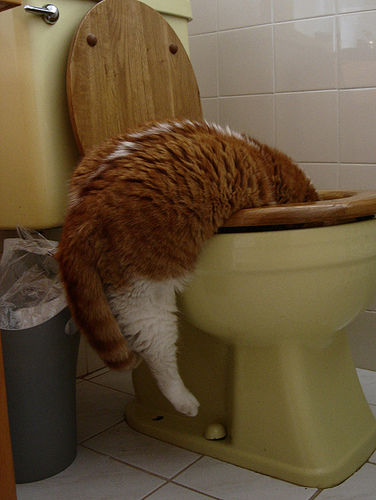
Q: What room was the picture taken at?
A: It was taken at the bathroom.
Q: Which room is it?
A: It is a bathroom.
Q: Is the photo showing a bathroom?
A: Yes, it is showing a bathroom.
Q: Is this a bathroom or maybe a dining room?
A: It is a bathroom.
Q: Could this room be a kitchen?
A: No, it is a bathroom.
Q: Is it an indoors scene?
A: Yes, it is indoors.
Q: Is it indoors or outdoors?
A: It is indoors.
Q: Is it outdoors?
A: No, it is indoors.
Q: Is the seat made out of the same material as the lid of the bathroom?
A: Yes, both the seat and the lid are made of wood.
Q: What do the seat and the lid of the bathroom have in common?
A: The material, both the seat and the lid are wooden.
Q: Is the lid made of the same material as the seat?
A: Yes, both the lid and the seat are made of wood.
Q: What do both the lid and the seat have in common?
A: The material, both the lid and the seat are wooden.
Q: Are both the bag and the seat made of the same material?
A: No, the bag is made of plastic and the seat is made of wood.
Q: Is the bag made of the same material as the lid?
A: No, the bag is made of plastic and the lid is made of wood.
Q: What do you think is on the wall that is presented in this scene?
A: The tiles are on the wall.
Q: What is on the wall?
A: The tiles are on the wall.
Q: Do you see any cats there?
A: Yes, there is a cat.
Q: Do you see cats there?
A: Yes, there is a cat.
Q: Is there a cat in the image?
A: Yes, there is a cat.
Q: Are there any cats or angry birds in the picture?
A: Yes, there is a cat.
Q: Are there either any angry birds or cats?
A: Yes, there is a cat.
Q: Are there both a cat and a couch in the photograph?
A: No, there is a cat but no couches.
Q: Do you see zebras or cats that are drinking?
A: Yes, the cat is drinking.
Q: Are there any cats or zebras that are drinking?
A: Yes, the cat is drinking.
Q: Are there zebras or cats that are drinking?
A: Yes, the cat is drinking.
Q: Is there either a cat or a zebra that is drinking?
A: Yes, the cat is drinking.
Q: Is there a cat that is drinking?
A: Yes, there is a cat that is drinking.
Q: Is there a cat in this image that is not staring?
A: Yes, there is a cat that is drinking.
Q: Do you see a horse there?
A: No, there are no horses.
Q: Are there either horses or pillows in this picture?
A: No, there are no horses or pillows.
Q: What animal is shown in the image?
A: The animal is a cat.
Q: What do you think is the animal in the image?
A: The animal is a cat.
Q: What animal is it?
A: The animal is a cat.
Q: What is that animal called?
A: This is a cat.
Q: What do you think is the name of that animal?
A: This is a cat.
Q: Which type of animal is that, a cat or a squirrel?
A: This is a cat.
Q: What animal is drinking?
A: The animal is a cat.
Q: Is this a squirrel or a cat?
A: This is a cat.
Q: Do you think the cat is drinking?
A: Yes, the cat is drinking.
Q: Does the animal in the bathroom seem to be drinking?
A: Yes, the cat is drinking.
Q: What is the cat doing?
A: The cat is drinking.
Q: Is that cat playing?
A: No, the cat is drinking.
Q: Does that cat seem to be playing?
A: No, the cat is drinking.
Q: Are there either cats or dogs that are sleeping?
A: No, there is a cat but it is drinking.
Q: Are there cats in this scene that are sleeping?
A: No, there is a cat but it is drinking.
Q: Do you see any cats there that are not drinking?
A: No, there is a cat but it is drinking.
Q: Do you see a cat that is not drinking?
A: No, there is a cat but it is drinking.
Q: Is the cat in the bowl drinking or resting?
A: The cat is drinking.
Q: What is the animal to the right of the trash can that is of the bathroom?
A: The animal is a cat.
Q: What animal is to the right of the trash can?
A: The animal is a cat.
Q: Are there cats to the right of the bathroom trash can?
A: Yes, there is a cat to the right of the trash can.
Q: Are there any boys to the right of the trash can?
A: No, there is a cat to the right of the trash can.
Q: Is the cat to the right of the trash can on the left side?
A: Yes, the cat is to the right of the trash can.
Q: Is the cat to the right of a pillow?
A: No, the cat is to the right of the trash can.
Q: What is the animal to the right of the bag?
A: The animal is a cat.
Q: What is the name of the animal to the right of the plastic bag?
A: The animal is a cat.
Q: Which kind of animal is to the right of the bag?
A: The animal is a cat.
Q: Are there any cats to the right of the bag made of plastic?
A: Yes, there is a cat to the right of the bag.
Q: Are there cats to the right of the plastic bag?
A: Yes, there is a cat to the right of the bag.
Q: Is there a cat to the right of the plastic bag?
A: Yes, there is a cat to the right of the bag.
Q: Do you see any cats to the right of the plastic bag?
A: Yes, there is a cat to the right of the bag.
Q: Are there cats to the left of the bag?
A: No, the cat is to the right of the bag.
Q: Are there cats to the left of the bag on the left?
A: No, the cat is to the right of the bag.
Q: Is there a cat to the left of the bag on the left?
A: No, the cat is to the right of the bag.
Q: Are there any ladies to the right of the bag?
A: No, there is a cat to the right of the bag.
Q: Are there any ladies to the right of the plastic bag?
A: No, there is a cat to the right of the bag.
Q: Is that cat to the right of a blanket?
A: No, the cat is to the right of the bag.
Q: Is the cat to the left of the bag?
A: No, the cat is to the right of the bag.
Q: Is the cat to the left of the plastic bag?
A: No, the cat is to the right of the bag.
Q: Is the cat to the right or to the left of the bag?
A: The cat is to the right of the bag.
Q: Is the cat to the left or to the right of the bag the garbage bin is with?
A: The cat is to the right of the bag.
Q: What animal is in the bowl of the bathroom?
A: The cat is in the bowl.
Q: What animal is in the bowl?
A: The cat is in the bowl.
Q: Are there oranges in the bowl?
A: No, there is a cat in the bowl.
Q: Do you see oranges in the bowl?
A: No, there is a cat in the bowl.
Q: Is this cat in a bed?
A: No, the cat is in a bowl.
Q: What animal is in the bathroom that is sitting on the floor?
A: The animal is a cat.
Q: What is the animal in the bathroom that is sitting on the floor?
A: The animal is a cat.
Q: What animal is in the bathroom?
A: The animal is a cat.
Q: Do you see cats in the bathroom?
A: Yes, there is a cat in the bathroom.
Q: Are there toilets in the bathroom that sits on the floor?
A: No, there is a cat in the bathroom.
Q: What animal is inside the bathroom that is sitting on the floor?
A: The cat is inside the bathroom.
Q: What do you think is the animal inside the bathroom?
A: The animal is a cat.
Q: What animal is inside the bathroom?
A: The animal is a cat.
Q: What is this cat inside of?
A: The cat is inside the bathroom.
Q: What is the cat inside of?
A: The cat is inside the bathroom.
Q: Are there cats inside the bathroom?
A: Yes, there is a cat inside the bathroom.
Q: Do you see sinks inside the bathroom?
A: No, there is a cat inside the bathroom.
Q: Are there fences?
A: No, there are no fences.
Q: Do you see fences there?
A: No, there are no fences.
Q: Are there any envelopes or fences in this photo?
A: No, there are no fences or envelopes.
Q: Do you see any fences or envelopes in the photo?
A: No, there are no fences or envelopes.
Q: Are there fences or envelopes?
A: No, there are no fences or envelopes.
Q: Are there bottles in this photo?
A: No, there are no bottles.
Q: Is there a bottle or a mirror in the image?
A: No, there are no bottles or mirrors.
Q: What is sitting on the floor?
A: The bathroom is sitting on the floor.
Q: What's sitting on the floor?
A: The bathroom is sitting on the floor.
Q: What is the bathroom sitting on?
A: The bathroom is sitting on the floor.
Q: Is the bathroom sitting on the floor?
A: Yes, the bathroom is sitting on the floor.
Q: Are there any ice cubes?
A: No, there are no ice cubes.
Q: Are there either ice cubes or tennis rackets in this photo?
A: No, there are no ice cubes or tennis rackets.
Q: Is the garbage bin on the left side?
A: Yes, the garbage bin is on the left of the image.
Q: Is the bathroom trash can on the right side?
A: No, the trashcan is on the left of the image.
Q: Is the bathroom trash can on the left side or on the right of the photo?
A: The trash can is on the left of the image.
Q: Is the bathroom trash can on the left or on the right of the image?
A: The trash can is on the left of the image.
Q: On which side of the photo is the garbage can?
A: The garbage can is on the left of the image.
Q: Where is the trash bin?
A: The trash bin is in the bathroom.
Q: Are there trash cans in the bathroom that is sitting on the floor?
A: Yes, there is a trash can in the bathroom.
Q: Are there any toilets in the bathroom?
A: No, there is a trash can in the bathroom.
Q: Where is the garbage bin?
A: The garbage bin is on the floor.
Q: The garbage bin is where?
A: The garbage bin is on the floor.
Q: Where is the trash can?
A: The garbage bin is on the floor.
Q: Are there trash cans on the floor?
A: Yes, there is a trash can on the floor.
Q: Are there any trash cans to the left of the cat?
A: Yes, there is a trash can to the left of the cat.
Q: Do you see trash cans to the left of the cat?
A: Yes, there is a trash can to the left of the cat.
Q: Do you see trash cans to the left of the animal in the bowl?
A: Yes, there is a trash can to the left of the cat.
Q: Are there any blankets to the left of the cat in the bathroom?
A: No, there is a trash can to the left of the cat.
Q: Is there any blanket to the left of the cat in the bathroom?
A: No, there is a trash can to the left of the cat.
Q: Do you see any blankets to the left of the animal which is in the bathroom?
A: No, there is a trash can to the left of the cat.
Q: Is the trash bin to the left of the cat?
A: Yes, the trash bin is to the left of the cat.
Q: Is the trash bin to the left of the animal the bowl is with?
A: Yes, the trash bin is to the left of the cat.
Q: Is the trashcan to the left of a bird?
A: No, the trashcan is to the left of the cat.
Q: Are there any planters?
A: No, there are no planters.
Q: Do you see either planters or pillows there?
A: No, there are no planters or pillows.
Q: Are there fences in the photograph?
A: No, there are no fences.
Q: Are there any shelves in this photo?
A: No, there are no shelves.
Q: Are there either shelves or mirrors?
A: No, there are no shelves or mirrors.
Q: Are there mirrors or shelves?
A: No, there are no shelves or mirrors.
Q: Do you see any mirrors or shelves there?
A: No, there are no shelves or mirrors.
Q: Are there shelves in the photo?
A: No, there are no shelves.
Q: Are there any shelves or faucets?
A: No, there are no shelves or faucets.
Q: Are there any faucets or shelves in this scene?
A: No, there are no shelves or faucets.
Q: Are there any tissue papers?
A: No, there are no tissue papers.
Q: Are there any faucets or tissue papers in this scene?
A: No, there are no tissue papers or faucets.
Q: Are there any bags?
A: Yes, there is a bag.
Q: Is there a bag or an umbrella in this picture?
A: Yes, there is a bag.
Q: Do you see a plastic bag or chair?
A: Yes, there is a plastic bag.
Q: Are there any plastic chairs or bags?
A: Yes, there is a plastic bag.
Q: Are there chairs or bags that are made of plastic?
A: Yes, the bag is made of plastic.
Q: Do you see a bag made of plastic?
A: Yes, there is a bag that is made of plastic.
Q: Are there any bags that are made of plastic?
A: Yes, there is a bag that is made of plastic.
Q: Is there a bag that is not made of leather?
A: Yes, there is a bag that is made of plastic.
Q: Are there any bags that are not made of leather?
A: Yes, there is a bag that is made of plastic.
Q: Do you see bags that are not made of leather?
A: Yes, there is a bag that is made of plastic.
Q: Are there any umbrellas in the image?
A: No, there are no umbrellas.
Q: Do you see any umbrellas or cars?
A: No, there are no umbrellas or cars.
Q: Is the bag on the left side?
A: Yes, the bag is on the left of the image.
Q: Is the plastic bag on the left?
A: Yes, the bag is on the left of the image.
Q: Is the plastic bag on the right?
A: No, the bag is on the left of the image.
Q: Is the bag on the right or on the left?
A: The bag is on the left of the image.